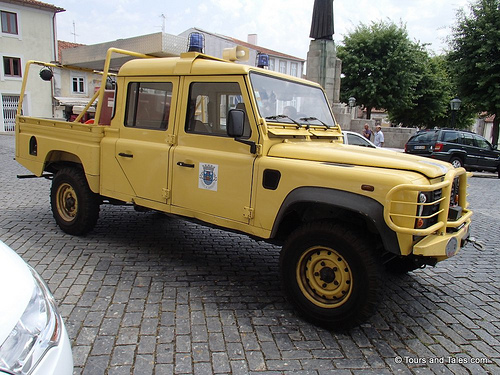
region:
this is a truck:
[11, 17, 478, 336]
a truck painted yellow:
[11, 37, 491, 324]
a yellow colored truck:
[5, 26, 465, 318]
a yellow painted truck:
[8, 37, 473, 334]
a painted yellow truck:
[19, 43, 481, 335]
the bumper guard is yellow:
[377, 161, 487, 268]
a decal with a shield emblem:
[190, 155, 231, 198]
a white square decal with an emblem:
[190, 158, 235, 213]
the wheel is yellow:
[283, 235, 364, 315]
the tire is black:
[262, 209, 397, 338]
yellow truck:
[11, 39, 476, 293]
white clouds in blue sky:
[385, 1, 422, 26]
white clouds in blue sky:
[414, 5, 451, 45]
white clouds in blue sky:
[358, 6, 388, 27]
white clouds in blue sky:
[252, 2, 299, 49]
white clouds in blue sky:
[215, 9, 246, 34]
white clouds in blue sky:
[232, 5, 286, 33]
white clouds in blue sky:
[170, 5, 220, 30]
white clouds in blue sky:
[98, 8, 136, 30]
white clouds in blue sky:
[71, 5, 108, 30]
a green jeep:
[411, 123, 498, 178]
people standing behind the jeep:
[356, 123, 397, 160]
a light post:
[448, 98, 459, 132]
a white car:
[4, 248, 89, 372]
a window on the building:
[1, 58, 27, 76]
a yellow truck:
[14, 50, 471, 310]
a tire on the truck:
[283, 230, 380, 344]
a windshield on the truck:
[253, 75, 327, 124]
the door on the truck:
[177, 82, 267, 214]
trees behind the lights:
[351, 50, 453, 122]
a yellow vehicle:
[6, 26, 491, 337]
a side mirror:
[223, 105, 260, 152]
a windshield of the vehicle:
[245, 65, 337, 127]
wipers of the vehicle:
[262, 112, 333, 132]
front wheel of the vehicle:
[272, 214, 393, 337]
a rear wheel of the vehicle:
[47, 162, 104, 240]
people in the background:
[360, 116, 387, 148]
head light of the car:
[0, 266, 59, 373]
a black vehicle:
[401, 121, 498, 176]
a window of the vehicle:
[181, 75, 253, 142]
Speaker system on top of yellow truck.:
[223, 44, 251, 61]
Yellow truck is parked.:
[16, 46, 471, 334]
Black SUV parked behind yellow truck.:
[403, 128, 499, 175]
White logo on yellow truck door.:
[197, 163, 218, 191]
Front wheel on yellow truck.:
[277, 221, 374, 333]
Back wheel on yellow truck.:
[50, 168, 98, 239]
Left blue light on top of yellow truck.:
[187, 31, 207, 53]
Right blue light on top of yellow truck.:
[257, 51, 269, 68]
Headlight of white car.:
[1, 264, 62, 374]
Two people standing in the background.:
[361, 123, 383, 147]